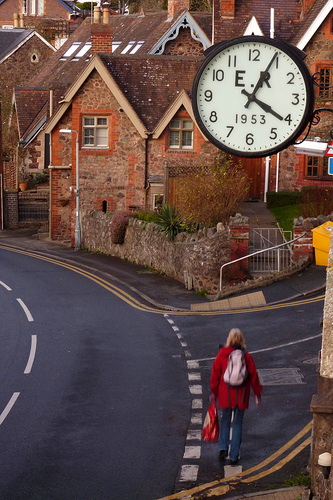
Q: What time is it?
A: 4:05.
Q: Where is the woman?
A: On the road.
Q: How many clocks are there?
A: 1.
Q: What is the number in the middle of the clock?
A: 1953.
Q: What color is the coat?
A: Red.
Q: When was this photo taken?
A: During the day.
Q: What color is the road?
A: Black.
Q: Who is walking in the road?
A: A woman.